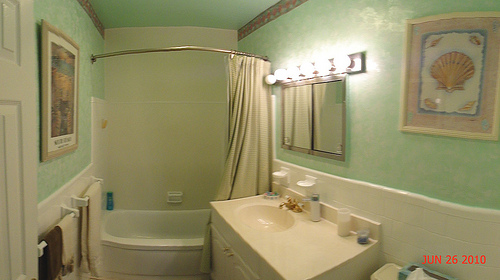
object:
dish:
[166, 192, 183, 204]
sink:
[235, 202, 297, 234]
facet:
[279, 198, 303, 213]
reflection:
[278, 80, 347, 158]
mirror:
[281, 75, 347, 161]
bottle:
[311, 193, 321, 222]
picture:
[399, 8, 498, 142]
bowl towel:
[41, 226, 63, 280]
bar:
[38, 206, 81, 258]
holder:
[166, 191, 183, 203]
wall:
[96, 0, 229, 213]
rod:
[37, 207, 81, 257]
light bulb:
[264, 75, 276, 86]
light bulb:
[274, 69, 291, 81]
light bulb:
[285, 66, 300, 81]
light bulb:
[299, 63, 316, 78]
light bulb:
[314, 56, 333, 76]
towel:
[81, 181, 117, 280]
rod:
[69, 177, 104, 209]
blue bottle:
[107, 191, 114, 210]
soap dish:
[166, 191, 185, 205]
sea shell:
[430, 51, 476, 94]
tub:
[92, 207, 211, 280]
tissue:
[403, 267, 436, 280]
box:
[395, 264, 446, 280]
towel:
[54, 214, 79, 280]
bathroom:
[2, 0, 500, 280]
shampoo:
[106, 191, 115, 210]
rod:
[90, 44, 269, 63]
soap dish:
[296, 175, 318, 188]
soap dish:
[271, 166, 291, 186]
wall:
[236, 0, 500, 280]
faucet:
[279, 196, 303, 212]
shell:
[429, 50, 476, 94]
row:
[263, 51, 370, 89]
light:
[264, 74, 277, 84]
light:
[273, 69, 290, 81]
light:
[285, 65, 302, 81]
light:
[299, 61, 315, 78]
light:
[314, 56, 333, 77]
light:
[331, 53, 351, 74]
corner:
[102, 16, 116, 217]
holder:
[65, 176, 103, 208]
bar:
[72, 176, 105, 208]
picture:
[34, 19, 82, 164]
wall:
[0, 0, 107, 238]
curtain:
[196, 54, 275, 277]